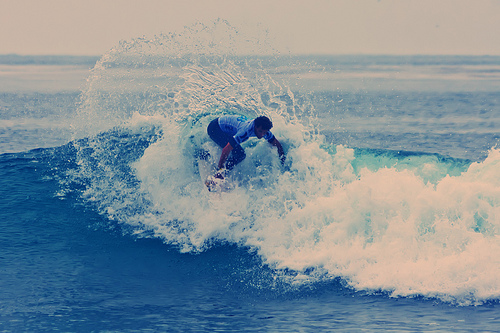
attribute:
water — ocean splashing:
[16, 63, 348, 247]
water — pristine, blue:
[31, 208, 146, 307]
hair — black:
[252, 113, 272, 129]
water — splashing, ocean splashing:
[0, 51, 498, 331]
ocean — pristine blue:
[0, 48, 499, 331]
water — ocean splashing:
[41, 241, 162, 326]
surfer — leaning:
[184, 95, 356, 196]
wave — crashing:
[0, 108, 497, 308]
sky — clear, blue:
[324, 17, 454, 45]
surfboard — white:
[192, 137, 267, 194]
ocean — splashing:
[55, 251, 254, 321]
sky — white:
[0, 0, 499, 59]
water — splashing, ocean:
[124, 76, 421, 316]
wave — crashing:
[2, 72, 497, 309]